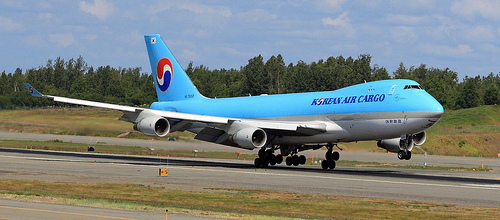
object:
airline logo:
[154, 56, 173, 93]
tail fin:
[141, 33, 212, 102]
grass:
[0, 103, 499, 219]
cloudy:
[77, 16, 289, 60]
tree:
[64, 54, 89, 90]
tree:
[239, 53, 265, 94]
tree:
[275, 54, 287, 93]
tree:
[292, 58, 310, 89]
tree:
[343, 51, 382, 86]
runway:
[0, 130, 499, 208]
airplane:
[21, 33, 445, 169]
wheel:
[395, 149, 412, 160]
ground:
[0, 104, 499, 219]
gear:
[319, 159, 337, 169]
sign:
[157, 167, 171, 176]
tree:
[25, 57, 52, 105]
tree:
[300, 57, 326, 91]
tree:
[119, 65, 139, 101]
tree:
[184, 59, 200, 93]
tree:
[0, 67, 14, 97]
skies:
[0, 0, 499, 83]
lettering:
[308, 93, 386, 106]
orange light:
[157, 167, 169, 176]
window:
[402, 84, 410, 90]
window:
[410, 84, 419, 88]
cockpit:
[400, 83, 424, 90]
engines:
[192, 119, 270, 150]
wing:
[22, 81, 328, 150]